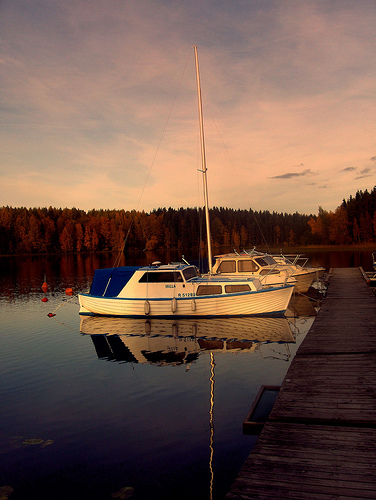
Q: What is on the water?
A: Reflection of the boat.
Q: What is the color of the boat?
A: White and blue.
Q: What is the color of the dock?
A: Brown.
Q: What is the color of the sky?
A: White and blue.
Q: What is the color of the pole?
A: Silver.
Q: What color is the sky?
A: Blue.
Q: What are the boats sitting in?
A: Water.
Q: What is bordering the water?
A: Trees.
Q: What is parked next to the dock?
A: Boats.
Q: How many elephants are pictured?
A: Zero.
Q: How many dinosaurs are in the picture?
A: Zero.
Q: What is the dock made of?
A: Wood.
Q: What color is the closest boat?
A: White and blue.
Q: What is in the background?
A: Trees.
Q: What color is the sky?
A: Blue.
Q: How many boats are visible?
A: Two.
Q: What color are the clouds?
A: White and pink.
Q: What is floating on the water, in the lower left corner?
A: Lily pads.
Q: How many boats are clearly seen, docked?
A: Two.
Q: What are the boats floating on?
A: Water.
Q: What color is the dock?
A: Dark brown.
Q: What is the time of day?
A: Twilight.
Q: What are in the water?
A: Boats.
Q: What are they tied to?
A: A pier.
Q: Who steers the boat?
A: The captain.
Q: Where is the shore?
A: At the end of the pier.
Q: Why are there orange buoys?
A: To note the channel.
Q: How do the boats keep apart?
A: They have bumpers.